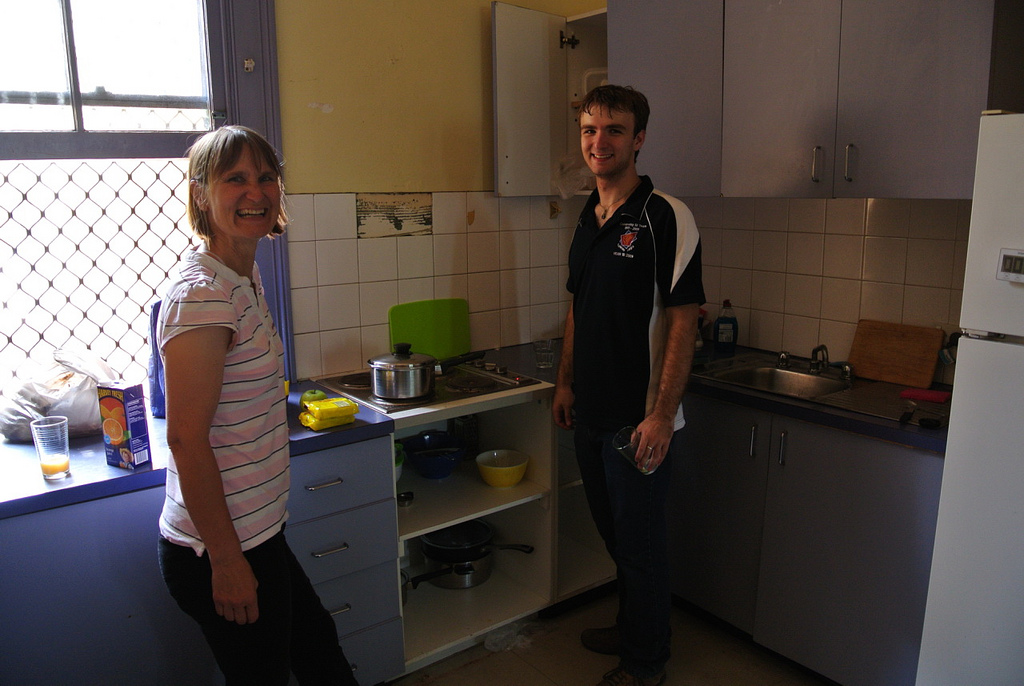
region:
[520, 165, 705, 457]
THE MAN IS WEARING A BLACK AND WHITE SHIRT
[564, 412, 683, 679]
THE MAN IS WEARING JEANS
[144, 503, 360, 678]
THE WOMAN IS WEARING BLACK PANTS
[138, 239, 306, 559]
THE WOMAN IS WEARING A SHORT SLEEVED SHIRT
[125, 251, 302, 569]
THIS SHIRT HAS STRIPES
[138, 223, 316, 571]
THIS SHIRT IS PINK AND WHITE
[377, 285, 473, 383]
THE CUTTING BOARD IS GREEN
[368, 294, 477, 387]
THIS IS A CUTTING BOARD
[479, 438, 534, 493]
a yellow bowl on a shelf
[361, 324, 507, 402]
a silver pot with a black handle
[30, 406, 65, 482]
a clear glass on a counter top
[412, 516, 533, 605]
a stack of pots and pans on a shelf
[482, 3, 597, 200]
a open cabinet door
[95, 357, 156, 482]
a carton of juice on a counter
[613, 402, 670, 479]
a man holding a glass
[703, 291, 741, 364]
a plastic bottle of dish liquid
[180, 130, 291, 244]
a woman with short hair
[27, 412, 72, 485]
A glass with a small amount of orange juice in it.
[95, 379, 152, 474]
A carton of orange juice.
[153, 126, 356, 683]
A woman wearing a white and pink striped shirt.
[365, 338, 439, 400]
A covered metal cooking pot.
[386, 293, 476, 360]
A green cutting board.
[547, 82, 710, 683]
A man wearing a black shirt with white accents.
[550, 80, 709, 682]
A man holding a glass in his left hand.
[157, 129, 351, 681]
thin woman wearing black pants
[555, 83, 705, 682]
man wearing a black and white shirt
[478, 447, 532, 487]
a yellow and white bowl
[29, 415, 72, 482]
orange juice in a glass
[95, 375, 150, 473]
a purple small box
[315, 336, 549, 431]
a silver pot on a black burner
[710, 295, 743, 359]
a bottle with a red cap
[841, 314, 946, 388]
a wooden cutter board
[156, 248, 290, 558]
a pink and white shirt with black lines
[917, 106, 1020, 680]
a white clean refrigerator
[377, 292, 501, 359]
A green cutting board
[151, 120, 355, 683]
older woman smiling for camera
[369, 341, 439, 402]
pot with lid on stove range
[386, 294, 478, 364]
green plastic board leaning against wall behind range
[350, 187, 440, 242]
bare area of wall missing two tiles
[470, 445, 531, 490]
yellow mixing bowl on shelf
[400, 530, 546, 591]
stack of pots and pans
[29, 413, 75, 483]
leftover orange juice in drinking glass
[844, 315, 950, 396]
wooden cutting board leaning against wall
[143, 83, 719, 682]
two people standing in a kitchen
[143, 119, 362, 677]
woman with a striped shirt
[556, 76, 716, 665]
man with a black and white shirt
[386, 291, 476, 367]
green cutting board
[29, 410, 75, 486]
glass of orange juice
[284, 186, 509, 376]
wall with missing tile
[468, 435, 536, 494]
small yellow bowl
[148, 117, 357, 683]
woman is wearing a pink and white striped shirt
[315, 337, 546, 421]
stainless steel pot on stovetop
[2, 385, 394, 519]
glass of juice on blue counter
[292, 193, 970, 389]
green cutting board leaning on tile backsplash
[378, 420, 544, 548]
yellow bowl on shelf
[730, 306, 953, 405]
wooden cutting board behind sink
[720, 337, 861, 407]
faucet for stainless steel sink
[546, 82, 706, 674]
man is holding an empty glass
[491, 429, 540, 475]
a pot on the shelf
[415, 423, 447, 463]
a pot on the shelf